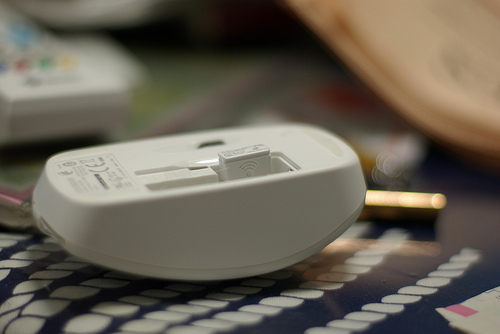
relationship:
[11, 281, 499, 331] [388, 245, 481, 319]
cloth with design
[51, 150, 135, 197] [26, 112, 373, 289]
label on mouse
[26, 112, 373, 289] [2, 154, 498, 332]
mouse on foreground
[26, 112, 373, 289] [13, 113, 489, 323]
mouse on table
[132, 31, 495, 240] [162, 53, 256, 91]
table has cloth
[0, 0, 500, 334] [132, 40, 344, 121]
table has cloth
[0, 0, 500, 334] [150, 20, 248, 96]
table has cloth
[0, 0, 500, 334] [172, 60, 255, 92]
table has cloth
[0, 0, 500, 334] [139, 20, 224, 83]
table has cloth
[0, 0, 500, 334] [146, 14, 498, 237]
table has cloth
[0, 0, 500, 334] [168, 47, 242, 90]
table has cloth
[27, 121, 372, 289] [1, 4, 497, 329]
mouse on desk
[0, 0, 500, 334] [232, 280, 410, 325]
table has polkadot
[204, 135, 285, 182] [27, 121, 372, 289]
wifi symbol on mouse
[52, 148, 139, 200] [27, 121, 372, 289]
text on mouse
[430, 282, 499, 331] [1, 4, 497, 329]
paper on desk